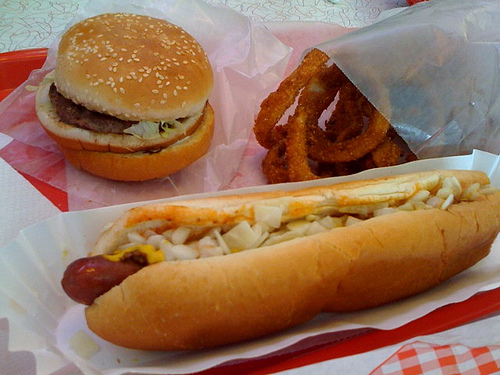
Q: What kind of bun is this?
A: Hot dog bun.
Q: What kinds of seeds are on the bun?
A: Sesame.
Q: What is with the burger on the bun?
A: Lettuce.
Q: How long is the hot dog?
A: Footlong.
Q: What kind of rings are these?
A: Onion.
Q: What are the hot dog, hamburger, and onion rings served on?
A: Lunch tray.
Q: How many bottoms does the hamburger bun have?
A: Two.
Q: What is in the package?
A: Onion rings.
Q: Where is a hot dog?
A: In a bun.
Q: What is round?
A: Hamburger.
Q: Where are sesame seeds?
A: On hamburger bun.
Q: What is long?
A: The hot dog.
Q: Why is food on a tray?
A: To be eaten.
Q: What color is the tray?
A: Red.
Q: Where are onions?
A: On the hot dog.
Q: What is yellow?
A: Mustard.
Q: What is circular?
A: Onion rings.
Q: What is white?
A: Paper on tray.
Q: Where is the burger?
A: In a tray.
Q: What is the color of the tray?
A: Red.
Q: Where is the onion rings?
A: In a paper.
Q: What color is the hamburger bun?
A: Brown.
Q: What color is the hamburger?
A: Brown.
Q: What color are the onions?
A: White.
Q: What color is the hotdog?
A: Red.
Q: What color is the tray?
A: Red.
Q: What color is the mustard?
A: Yellow.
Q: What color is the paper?
A: White.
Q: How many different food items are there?
A: 3.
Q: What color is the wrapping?
A: White.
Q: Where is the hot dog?
A: In the bun.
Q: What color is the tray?
A: Red.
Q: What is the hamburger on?
A: A bun.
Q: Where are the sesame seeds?
A: On the hamburger bun.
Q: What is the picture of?
A: Food.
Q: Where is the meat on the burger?
A: Between the buns.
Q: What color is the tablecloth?
A: Red and white.